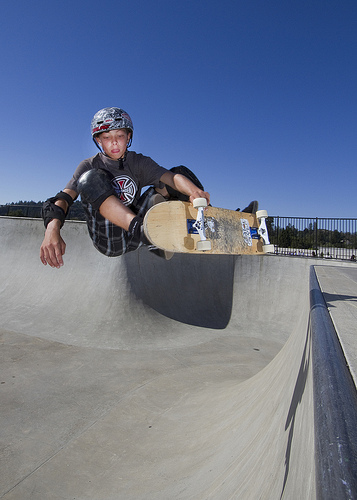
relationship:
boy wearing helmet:
[39, 105, 213, 299] [89, 106, 133, 146]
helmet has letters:
[89, 106, 133, 146] [90, 123, 109, 135]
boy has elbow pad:
[39, 105, 213, 299] [41, 190, 74, 227]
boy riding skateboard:
[39, 105, 213, 299] [141, 200, 276, 256]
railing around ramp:
[0, 202, 356, 267] [1, 214, 356, 499]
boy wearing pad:
[39, 105, 213, 299] [65, 165, 113, 213]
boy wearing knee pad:
[39, 105, 213, 299] [167, 161, 207, 201]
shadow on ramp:
[270, 286, 355, 499] [1, 214, 356, 499]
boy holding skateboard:
[39, 105, 213, 299] [141, 200, 276, 256]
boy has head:
[39, 105, 213, 299] [90, 106, 132, 162]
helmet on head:
[89, 106, 133, 146] [90, 106, 132, 162]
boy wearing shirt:
[39, 105, 213, 299] [65, 148, 164, 215]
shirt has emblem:
[65, 148, 164, 215] [105, 174, 139, 207]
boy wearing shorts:
[39, 105, 213, 299] [83, 183, 164, 258]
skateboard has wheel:
[141, 200, 276, 256] [193, 197, 209, 207]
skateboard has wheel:
[141, 200, 276, 256] [198, 239, 210, 252]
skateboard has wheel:
[141, 200, 276, 256] [254, 209, 269, 220]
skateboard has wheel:
[141, 200, 276, 256] [260, 244, 276, 258]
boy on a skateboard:
[39, 105, 213, 299] [141, 200, 276, 256]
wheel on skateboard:
[263, 244, 275, 254] [141, 200, 276, 256]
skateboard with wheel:
[141, 200, 276, 256] [261, 240, 273, 255]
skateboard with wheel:
[141, 200, 276, 256] [254, 209, 269, 219]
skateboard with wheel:
[141, 200, 276, 256] [193, 197, 209, 207]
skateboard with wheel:
[141, 200, 276, 256] [198, 239, 210, 252]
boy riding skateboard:
[30, 101, 218, 300] [141, 200, 276, 256]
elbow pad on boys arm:
[41, 190, 74, 227] [39, 158, 91, 268]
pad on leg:
[65, 165, 113, 213] [76, 170, 146, 239]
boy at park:
[39, 105, 213, 299] [0, 204, 355, 496]